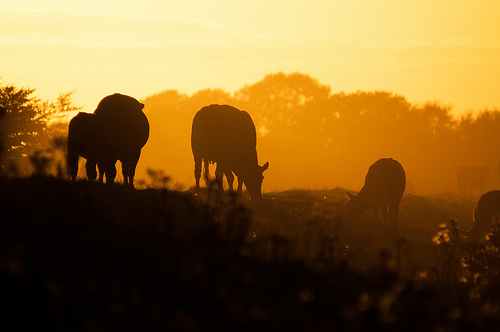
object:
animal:
[189, 104, 269, 201]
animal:
[342, 156, 406, 231]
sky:
[0, 1, 499, 105]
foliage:
[238, 70, 330, 167]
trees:
[0, 82, 57, 162]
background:
[0, 0, 498, 332]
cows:
[63, 91, 155, 189]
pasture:
[53, 188, 497, 265]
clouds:
[0, 0, 499, 77]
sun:
[0, 0, 499, 118]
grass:
[190, 188, 441, 287]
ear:
[134, 98, 148, 113]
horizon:
[5, 66, 499, 90]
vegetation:
[0, 139, 493, 331]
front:
[170, 275, 394, 328]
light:
[0, 0, 498, 95]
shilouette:
[189, 103, 268, 199]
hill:
[2, 176, 486, 330]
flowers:
[432, 229, 450, 248]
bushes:
[0, 177, 408, 331]